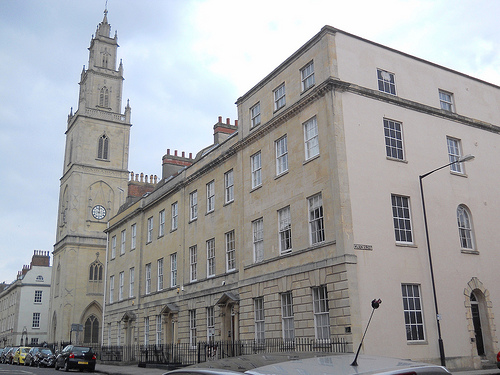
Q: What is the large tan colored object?
A: Building.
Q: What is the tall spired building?
A: Tower.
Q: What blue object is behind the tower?
A: The sky.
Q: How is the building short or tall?
A: Tall.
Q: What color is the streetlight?
A: Black.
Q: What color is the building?
A: Tan.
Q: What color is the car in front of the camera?
A: Silver.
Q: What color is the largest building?
A: Tan.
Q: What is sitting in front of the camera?
A: Silver car.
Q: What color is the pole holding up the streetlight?
A: Black.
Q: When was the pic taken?
A: During the day.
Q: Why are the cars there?
A: They are parked.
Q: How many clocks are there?
A: 1.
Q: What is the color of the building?
A: Cream.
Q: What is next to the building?
A: Fence.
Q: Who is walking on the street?
A: No one.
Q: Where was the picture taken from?
A: On the street.